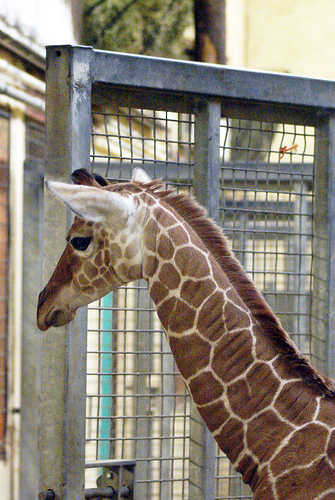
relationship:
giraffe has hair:
[36, 167, 324, 500] [144, 171, 334, 395]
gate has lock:
[39, 44, 333, 499] [40, 448, 134, 498]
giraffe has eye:
[36, 167, 324, 500] [68, 230, 100, 251]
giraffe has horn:
[36, 167, 324, 500] [74, 169, 99, 190]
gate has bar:
[39, 44, 333, 499] [192, 93, 219, 499]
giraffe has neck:
[36, 167, 324, 500] [147, 177, 334, 495]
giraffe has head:
[36, 167, 324, 500] [29, 167, 153, 336]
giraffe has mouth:
[36, 167, 324, 500] [33, 300, 80, 343]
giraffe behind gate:
[36, 167, 324, 500] [39, 44, 333, 499]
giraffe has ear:
[36, 167, 324, 500] [42, 178, 139, 226]